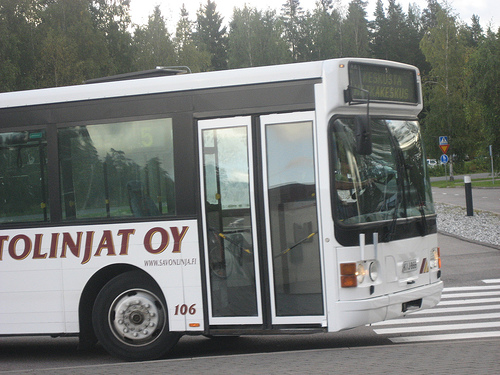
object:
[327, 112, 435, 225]
windshield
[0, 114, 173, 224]
windows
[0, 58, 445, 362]
bus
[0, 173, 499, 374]
pavement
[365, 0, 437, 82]
tree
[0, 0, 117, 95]
trees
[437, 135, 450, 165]
sign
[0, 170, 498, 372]
road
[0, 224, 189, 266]
writing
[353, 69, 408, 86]
writing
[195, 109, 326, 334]
door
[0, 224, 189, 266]
letters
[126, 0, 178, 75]
trees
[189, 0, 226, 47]
trees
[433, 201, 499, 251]
median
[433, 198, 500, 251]
path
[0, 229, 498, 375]
roadway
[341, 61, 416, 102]
sign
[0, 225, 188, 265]
name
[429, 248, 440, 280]
headlights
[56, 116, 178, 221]
glass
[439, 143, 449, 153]
yield sign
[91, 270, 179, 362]
left wheel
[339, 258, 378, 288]
headlights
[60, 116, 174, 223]
reflection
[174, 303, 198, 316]
number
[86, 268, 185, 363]
tire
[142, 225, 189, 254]
oy